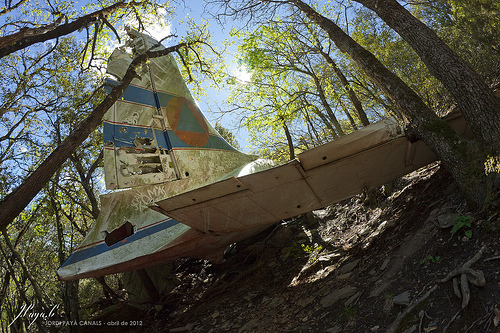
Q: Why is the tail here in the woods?
A: A plane crash.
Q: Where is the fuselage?
A: Behind the debris.